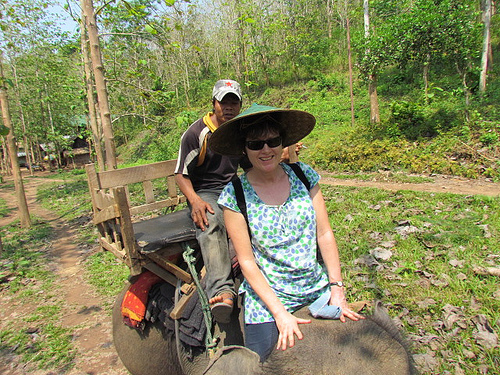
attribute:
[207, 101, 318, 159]
hat — weird, green, large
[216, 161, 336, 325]
design — blue, green, short sleeved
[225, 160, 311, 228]
straps — black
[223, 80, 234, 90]
star — red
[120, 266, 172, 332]
blanket — colorful, orange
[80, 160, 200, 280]
seat — wood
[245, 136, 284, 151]
sunglasses — dark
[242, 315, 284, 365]
jeans — blue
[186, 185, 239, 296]
jeans — blue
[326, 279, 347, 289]
watch — black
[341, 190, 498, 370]
leaves — brown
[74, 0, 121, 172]
trunks — brown, large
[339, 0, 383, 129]
trunks — brown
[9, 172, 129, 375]
path — large, brown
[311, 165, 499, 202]
path — brown